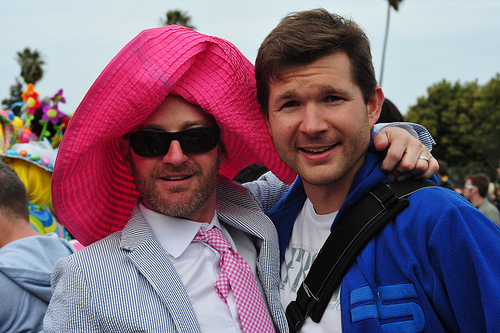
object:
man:
[40, 89, 440, 331]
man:
[2, 163, 79, 331]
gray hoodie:
[0, 232, 77, 333]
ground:
[402, 218, 432, 265]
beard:
[148, 173, 209, 217]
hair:
[255, 8, 378, 122]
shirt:
[139, 200, 277, 333]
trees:
[400, 71, 500, 189]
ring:
[418, 156, 429, 162]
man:
[76, 47, 295, 331]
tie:
[191, 226, 278, 333]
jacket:
[37, 120, 440, 332]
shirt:
[280, 204, 349, 324]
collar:
[138, 201, 222, 260]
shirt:
[137, 201, 255, 331]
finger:
[371, 126, 440, 182]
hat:
[50, 25, 298, 249]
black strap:
[283, 167, 439, 325]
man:
[265, 7, 500, 332]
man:
[55, 51, 296, 330]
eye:
[322, 95, 345, 104]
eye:
[279, 100, 301, 111]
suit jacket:
[53, 117, 305, 315]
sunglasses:
[119, 125, 222, 157]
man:
[36, 24, 444, 333]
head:
[116, 95, 227, 221]